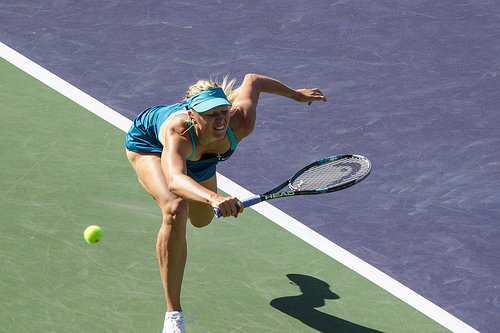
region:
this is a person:
[113, 47, 285, 330]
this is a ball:
[68, 221, 130, 276]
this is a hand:
[222, 56, 336, 143]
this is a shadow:
[268, 267, 383, 330]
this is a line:
[360, 244, 449, 326]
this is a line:
[265, 196, 365, 263]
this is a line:
[0, 30, 57, 103]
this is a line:
[65, 74, 127, 146]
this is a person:
[83, 70, 319, 322]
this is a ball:
[78, 222, 113, 255]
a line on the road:
[314, 222, 362, 281]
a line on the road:
[356, 252, 419, 320]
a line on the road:
[43, 67, 94, 136]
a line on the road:
[290, 227, 369, 286]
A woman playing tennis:
[129, 56, 325, 331]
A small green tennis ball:
[72, 227, 118, 250]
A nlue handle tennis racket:
[206, 151, 373, 236]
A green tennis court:
[215, 247, 368, 329]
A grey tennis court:
[384, 19, 498, 151]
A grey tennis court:
[256, 88, 373, 241]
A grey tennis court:
[61, 13, 264, 66]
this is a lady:
[92, 57, 328, 322]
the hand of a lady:
[208, 35, 339, 168]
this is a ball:
[77, 212, 113, 254]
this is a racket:
[202, 134, 385, 221]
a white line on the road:
[338, 245, 418, 320]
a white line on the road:
[308, 217, 374, 277]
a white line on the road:
[49, 43, 104, 118]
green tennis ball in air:
[82, 224, 104, 246]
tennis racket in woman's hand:
[213, 151, 373, 218]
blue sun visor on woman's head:
[178, 84, 230, 111]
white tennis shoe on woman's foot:
[161, 310, 186, 331]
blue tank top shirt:
[143, 103, 242, 172]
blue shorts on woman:
[125, 120, 219, 182]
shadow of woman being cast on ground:
[269, 271, 375, 331]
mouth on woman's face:
[214, 123, 226, 131]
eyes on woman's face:
[205, 108, 229, 118]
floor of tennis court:
[2, 2, 499, 332]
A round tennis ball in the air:
[75, 213, 111, 251]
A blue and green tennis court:
[0, 0, 495, 326]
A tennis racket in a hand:
[206, 141, 376, 221]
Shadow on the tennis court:
[260, 255, 391, 327]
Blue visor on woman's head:
[175, 65, 237, 140]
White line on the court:
[0, 31, 486, 328]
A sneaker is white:
[155, 301, 191, 331]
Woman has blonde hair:
[180, 60, 241, 140]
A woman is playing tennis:
[115, 46, 385, 326]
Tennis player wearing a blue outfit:
[120, 68, 248, 189]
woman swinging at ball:
[66, 63, 376, 299]